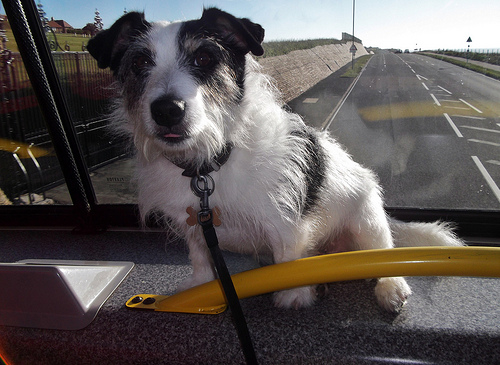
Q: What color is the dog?
A: Black and white.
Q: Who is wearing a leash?
A: The dog.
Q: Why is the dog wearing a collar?
A: To connect the leash.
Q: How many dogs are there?
A: One.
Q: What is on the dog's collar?
A: A tag.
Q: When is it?
A: Day time.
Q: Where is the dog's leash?
A: On the collar.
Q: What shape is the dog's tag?
A: Bone shape.